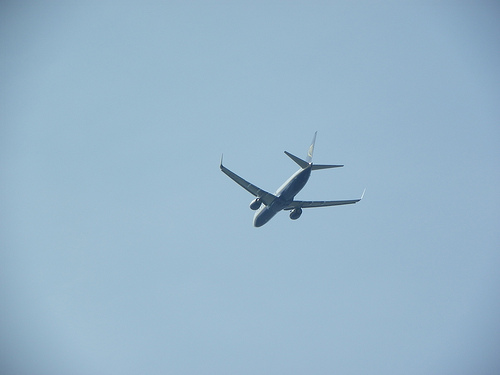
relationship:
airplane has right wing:
[219, 130, 366, 228] [289, 196, 363, 208]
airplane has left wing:
[219, 130, 366, 228] [217, 153, 274, 209]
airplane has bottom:
[219, 130, 366, 228] [254, 167, 310, 224]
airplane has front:
[219, 130, 366, 228] [250, 200, 278, 229]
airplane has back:
[219, 130, 366, 228] [277, 134, 344, 198]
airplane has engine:
[219, 130, 366, 228] [289, 206, 303, 222]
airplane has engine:
[219, 130, 366, 228] [249, 195, 264, 209]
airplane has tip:
[219, 130, 366, 228] [284, 132, 348, 175]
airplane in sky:
[219, 130, 366, 228] [1, 0, 499, 373]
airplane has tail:
[219, 130, 366, 228] [284, 132, 348, 175]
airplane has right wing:
[219, 130, 366, 228] [284, 188, 365, 209]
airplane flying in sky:
[219, 130, 366, 228] [1, 0, 499, 373]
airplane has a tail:
[219, 130, 366, 228] [284, 132, 348, 175]